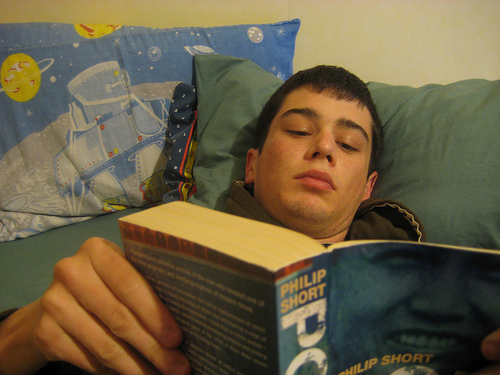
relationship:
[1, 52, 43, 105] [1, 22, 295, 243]
planet on pillow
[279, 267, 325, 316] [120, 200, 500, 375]
author of book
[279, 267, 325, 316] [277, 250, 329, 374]
author on binding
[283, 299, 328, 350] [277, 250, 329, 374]
letter on binding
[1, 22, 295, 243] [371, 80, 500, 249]
pillow on bed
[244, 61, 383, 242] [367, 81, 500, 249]
man laying on h pillow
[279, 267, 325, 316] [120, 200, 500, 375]
author on book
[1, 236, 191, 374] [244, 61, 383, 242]
hand of man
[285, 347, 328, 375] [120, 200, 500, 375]
letter on book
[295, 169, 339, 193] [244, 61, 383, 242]
lips on man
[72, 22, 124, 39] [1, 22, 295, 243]
planet on pillow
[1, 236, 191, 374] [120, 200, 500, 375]
hand holding onto book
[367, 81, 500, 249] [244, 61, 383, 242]
pillow under man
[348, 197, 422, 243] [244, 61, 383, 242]
hoodie on man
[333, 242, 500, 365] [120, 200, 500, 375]
face on book